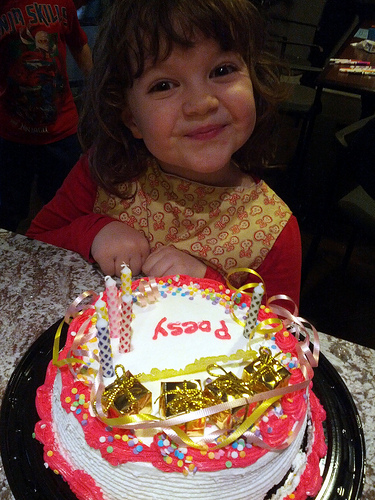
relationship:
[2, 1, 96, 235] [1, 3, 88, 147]
child wearing shirt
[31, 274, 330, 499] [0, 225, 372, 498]
cake on table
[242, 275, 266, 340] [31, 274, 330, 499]
candle on cake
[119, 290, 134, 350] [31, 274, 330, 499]
candle on cake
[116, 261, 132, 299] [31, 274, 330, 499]
candle on cake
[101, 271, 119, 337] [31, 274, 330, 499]
candle on cake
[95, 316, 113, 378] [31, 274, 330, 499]
candle on cake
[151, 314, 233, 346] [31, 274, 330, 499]
word on cake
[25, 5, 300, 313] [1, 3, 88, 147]
girl wearing a shirt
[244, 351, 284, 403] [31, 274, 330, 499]
box on top of cake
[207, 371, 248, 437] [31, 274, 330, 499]
box on top of cake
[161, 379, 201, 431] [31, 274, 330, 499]
box on top of cake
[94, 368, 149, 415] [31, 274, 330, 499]
box on top of cake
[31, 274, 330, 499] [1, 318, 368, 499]
cake on platter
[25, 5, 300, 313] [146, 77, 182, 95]
girl has eye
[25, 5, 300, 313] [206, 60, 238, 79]
girl has eye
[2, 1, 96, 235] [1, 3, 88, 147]
child wearing a shirt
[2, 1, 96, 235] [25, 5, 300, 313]
child behind girl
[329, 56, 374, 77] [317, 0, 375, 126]
pens are on top of desk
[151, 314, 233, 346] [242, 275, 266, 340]
word beside of candle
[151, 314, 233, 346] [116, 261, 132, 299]
word beside of candle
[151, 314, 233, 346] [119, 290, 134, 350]
word beside of candle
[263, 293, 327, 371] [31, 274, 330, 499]
ribbon on top of cake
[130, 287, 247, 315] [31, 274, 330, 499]
sprinkles are on cake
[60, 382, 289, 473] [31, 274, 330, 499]
sprinkles are on cake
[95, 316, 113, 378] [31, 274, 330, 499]
candle on top of cake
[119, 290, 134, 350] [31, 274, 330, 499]
candle on top of cake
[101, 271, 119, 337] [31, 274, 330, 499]
candle on top of cake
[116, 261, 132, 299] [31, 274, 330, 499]
candle on top of cake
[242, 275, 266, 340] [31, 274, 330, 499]
candle on top of cake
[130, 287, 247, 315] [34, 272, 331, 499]
sprinkles on top of cake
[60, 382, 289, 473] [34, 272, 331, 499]
sprinkles on top of cake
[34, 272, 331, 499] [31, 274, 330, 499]
cake on top of cake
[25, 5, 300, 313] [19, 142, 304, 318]
girl wearing shirt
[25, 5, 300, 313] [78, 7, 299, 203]
girl has hair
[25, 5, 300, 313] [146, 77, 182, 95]
girl has an eye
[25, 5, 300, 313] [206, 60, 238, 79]
girl has an eye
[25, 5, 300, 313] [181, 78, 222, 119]
girl has a nose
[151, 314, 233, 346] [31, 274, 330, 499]
word on top of cake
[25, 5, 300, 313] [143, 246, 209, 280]
girl has a hand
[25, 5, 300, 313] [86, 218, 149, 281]
girl has a hand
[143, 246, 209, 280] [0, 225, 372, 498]
hand on table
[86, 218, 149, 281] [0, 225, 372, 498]
hand on table